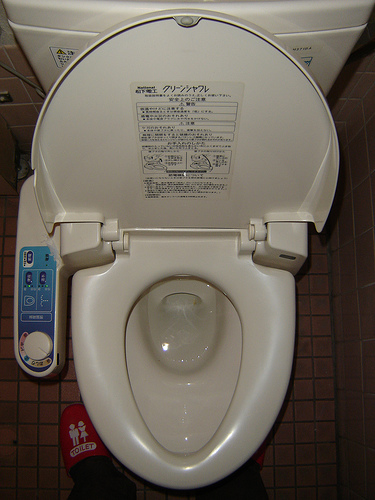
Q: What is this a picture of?
A: A toilet.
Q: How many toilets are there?
A: 1.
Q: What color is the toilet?
A: White.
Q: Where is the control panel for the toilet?
A: To the left side.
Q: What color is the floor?
A: Brown.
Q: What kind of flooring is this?
A: Tiles.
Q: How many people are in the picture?
A: None.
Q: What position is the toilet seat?
A: Down.